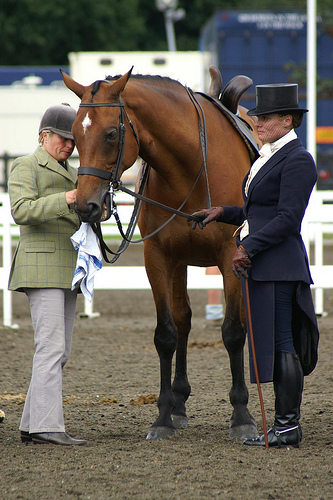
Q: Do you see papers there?
A: No, there are no papers.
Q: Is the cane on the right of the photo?
A: Yes, the cane is on the right of the image.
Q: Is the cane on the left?
A: No, the cane is on the right of the image.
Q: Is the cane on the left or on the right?
A: The cane is on the right of the image.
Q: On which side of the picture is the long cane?
A: The cane is on the right of the image.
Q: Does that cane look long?
A: Yes, the cane is long.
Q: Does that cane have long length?
A: Yes, the cane is long.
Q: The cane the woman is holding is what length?
A: The cane is long.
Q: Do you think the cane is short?
A: No, the cane is long.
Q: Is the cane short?
A: No, the cane is long.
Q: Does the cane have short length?
A: No, the cane is long.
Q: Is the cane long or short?
A: The cane is long.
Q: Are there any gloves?
A: Yes, there are gloves.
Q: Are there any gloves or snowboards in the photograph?
A: Yes, there are gloves.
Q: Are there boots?
A: Yes, there are boots.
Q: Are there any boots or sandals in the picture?
A: Yes, there are boots.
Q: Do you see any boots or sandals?
A: Yes, there are boots.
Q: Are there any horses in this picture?
A: Yes, there is a horse.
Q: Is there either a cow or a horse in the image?
A: Yes, there is a horse.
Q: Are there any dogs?
A: No, there are no dogs.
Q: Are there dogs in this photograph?
A: No, there are no dogs.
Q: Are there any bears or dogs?
A: No, there are no dogs or bears.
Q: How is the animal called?
A: The animal is a horse.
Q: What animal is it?
A: The animal is a horse.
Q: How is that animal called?
A: That is a horse.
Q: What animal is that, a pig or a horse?
A: That is a horse.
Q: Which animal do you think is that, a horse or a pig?
A: That is a horse.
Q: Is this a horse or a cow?
A: This is a horse.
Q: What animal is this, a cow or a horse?
A: This is a horse.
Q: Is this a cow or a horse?
A: This is a horse.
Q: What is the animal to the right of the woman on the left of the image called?
A: The animal is a horse.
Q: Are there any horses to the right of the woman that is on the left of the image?
A: Yes, there is a horse to the right of the woman.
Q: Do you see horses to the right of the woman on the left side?
A: Yes, there is a horse to the right of the woman.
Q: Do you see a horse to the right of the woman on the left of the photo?
A: Yes, there is a horse to the right of the woman.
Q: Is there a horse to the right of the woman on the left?
A: Yes, there is a horse to the right of the woman.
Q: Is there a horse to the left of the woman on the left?
A: No, the horse is to the right of the woman.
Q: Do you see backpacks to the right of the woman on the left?
A: No, there is a horse to the right of the woman.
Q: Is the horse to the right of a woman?
A: Yes, the horse is to the right of a woman.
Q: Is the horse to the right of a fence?
A: No, the horse is to the right of a woman.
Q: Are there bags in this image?
A: No, there are no bags.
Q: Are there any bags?
A: No, there are no bags.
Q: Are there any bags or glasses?
A: No, there are no bags or glasses.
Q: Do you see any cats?
A: No, there are no cats.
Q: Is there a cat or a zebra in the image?
A: No, there are no cats or zebras.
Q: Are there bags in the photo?
A: No, there are no bags.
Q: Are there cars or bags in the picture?
A: No, there are no bags or cars.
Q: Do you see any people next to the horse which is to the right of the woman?
A: Yes, there are people next to the horse.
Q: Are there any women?
A: Yes, there is a woman.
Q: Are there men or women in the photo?
A: Yes, there is a woman.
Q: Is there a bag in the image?
A: No, there are no bags.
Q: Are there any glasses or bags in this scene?
A: No, there are no bags or glasses.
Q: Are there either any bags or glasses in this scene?
A: No, there are no bags or glasses.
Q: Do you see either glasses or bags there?
A: No, there are no bags or glasses.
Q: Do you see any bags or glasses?
A: No, there are no bags or glasses.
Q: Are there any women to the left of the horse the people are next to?
A: Yes, there is a woman to the left of the horse.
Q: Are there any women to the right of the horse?
A: No, the woman is to the left of the horse.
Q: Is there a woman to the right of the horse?
A: No, the woman is to the left of the horse.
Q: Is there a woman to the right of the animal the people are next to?
A: No, the woman is to the left of the horse.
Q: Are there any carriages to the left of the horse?
A: No, there is a woman to the left of the horse.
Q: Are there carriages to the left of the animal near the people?
A: No, there is a woman to the left of the horse.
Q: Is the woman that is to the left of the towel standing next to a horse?
A: Yes, the woman is standing next to a horse.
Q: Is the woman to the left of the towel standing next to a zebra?
A: No, the woman is standing next to a horse.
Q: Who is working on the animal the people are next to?
A: The woman is working on the horse.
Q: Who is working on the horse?
A: The woman is working on the horse.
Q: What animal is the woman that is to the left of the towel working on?
A: The woman is working on the horse.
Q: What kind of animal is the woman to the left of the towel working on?
A: The woman is working on the horse.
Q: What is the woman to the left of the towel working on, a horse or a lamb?
A: The woman is working on a horse.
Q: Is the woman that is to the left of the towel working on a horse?
A: Yes, the woman is working on a horse.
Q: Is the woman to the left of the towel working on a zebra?
A: No, the woman is working on a horse.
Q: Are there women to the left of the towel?
A: Yes, there is a woman to the left of the towel.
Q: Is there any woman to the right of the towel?
A: No, the woman is to the left of the towel.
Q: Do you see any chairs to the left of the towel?
A: No, there is a woman to the left of the towel.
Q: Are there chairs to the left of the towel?
A: No, there is a woman to the left of the towel.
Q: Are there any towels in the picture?
A: Yes, there is a towel.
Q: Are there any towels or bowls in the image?
A: Yes, there is a towel.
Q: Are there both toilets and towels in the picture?
A: No, there is a towel but no toilets.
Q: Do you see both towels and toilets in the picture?
A: No, there is a towel but no toilets.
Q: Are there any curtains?
A: No, there are no curtains.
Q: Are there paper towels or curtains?
A: No, there are no curtains or paper towels.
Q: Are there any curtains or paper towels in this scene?
A: No, there are no curtains or paper towels.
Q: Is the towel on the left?
A: Yes, the towel is on the left of the image.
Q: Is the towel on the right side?
A: No, the towel is on the left of the image.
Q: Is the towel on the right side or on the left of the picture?
A: The towel is on the left of the image.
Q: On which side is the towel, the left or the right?
A: The towel is on the left of the image.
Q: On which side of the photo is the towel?
A: The towel is on the left of the image.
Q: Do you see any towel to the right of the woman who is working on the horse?
A: Yes, there is a towel to the right of the woman.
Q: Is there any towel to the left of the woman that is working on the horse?
A: No, the towel is to the right of the woman.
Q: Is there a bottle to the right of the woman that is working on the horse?
A: No, there is a towel to the right of the woman.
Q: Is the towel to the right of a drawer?
A: No, the towel is to the right of the woman.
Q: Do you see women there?
A: Yes, there is a woman.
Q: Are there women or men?
A: Yes, there is a woman.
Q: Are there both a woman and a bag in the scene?
A: No, there is a woman but no bags.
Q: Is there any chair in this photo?
A: No, there are no chairs.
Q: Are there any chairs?
A: No, there are no chairs.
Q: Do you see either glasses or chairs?
A: No, there are no chairs or glasses.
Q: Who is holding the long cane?
A: The woman is holding the cane.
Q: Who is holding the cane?
A: The woman is holding the cane.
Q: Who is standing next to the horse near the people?
A: The woman is standing next to the horse.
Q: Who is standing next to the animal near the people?
A: The woman is standing next to the horse.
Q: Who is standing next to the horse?
A: The woman is standing next to the horse.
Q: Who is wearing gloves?
A: The woman is wearing gloves.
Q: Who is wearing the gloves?
A: The woman is wearing gloves.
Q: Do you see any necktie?
A: No, there are no ties.